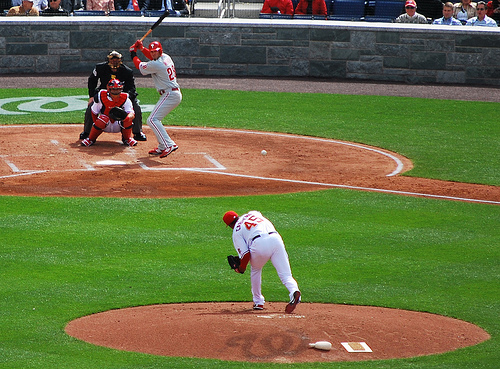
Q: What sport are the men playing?
A: Baseball.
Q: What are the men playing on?
A: A baseball field.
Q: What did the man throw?
A: A ball.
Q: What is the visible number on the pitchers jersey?
A: 45.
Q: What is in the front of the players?
A: A stone wall.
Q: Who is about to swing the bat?
A: The baseball player.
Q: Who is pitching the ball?
A: The pitcher.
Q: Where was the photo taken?
A: At a baseball game.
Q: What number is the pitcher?
A: 45.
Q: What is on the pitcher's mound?
A: Dirt.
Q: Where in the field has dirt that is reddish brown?
A: Infield.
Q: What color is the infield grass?
A: Green.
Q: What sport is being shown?
A: Baseball.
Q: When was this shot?
A: Daytime.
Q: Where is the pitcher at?
A: Pitchers mound.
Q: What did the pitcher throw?
A: Baseball.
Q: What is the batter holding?
A: Baseball bat.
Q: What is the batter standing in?
A: Batters box.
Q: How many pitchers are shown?
A: 1.